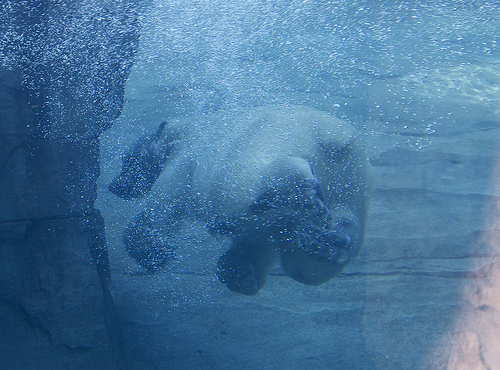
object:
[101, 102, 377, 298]
polar bear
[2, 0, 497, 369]
water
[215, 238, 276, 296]
legs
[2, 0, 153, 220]
rock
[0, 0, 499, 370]
bubbles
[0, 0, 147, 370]
wall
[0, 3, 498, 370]
tank